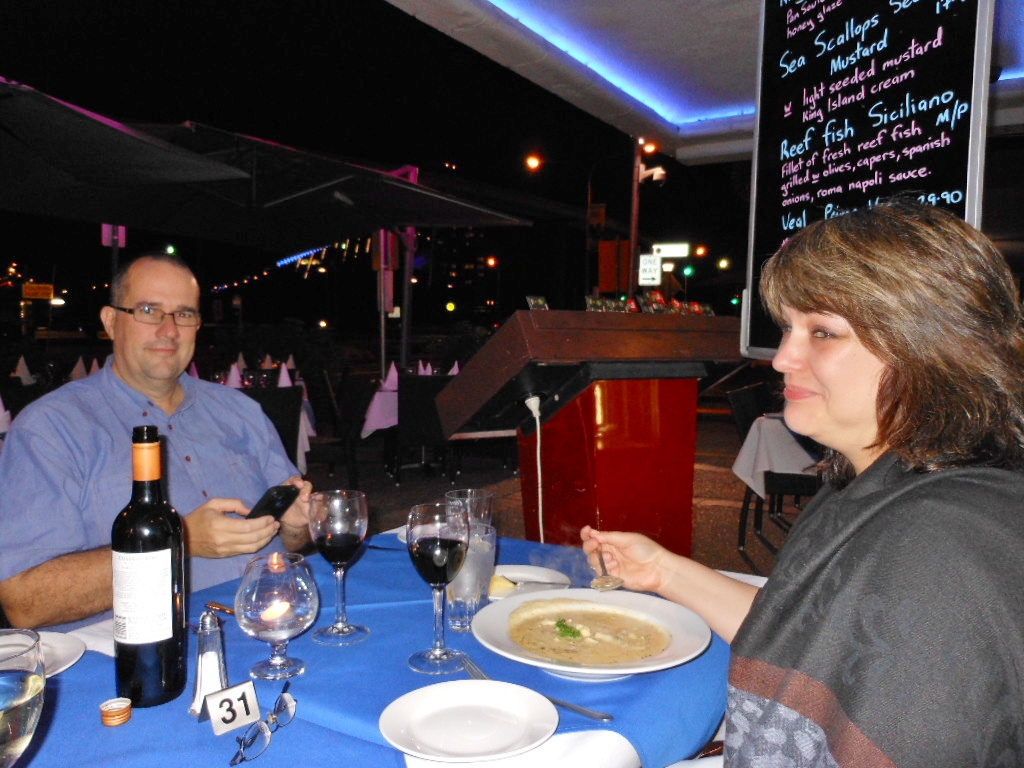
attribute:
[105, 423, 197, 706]
bottle — open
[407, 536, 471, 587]
wine — red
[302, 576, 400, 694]
tablecloth — blue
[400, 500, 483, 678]
wine glass — tall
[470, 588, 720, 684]
plate — large, white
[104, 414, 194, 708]
wine — tall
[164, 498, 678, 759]
tablecloth — blue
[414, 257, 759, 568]
podium — red, black, brown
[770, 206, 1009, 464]
hair — short, brown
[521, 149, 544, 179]
stage light — small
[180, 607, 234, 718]
salt shaker — tall